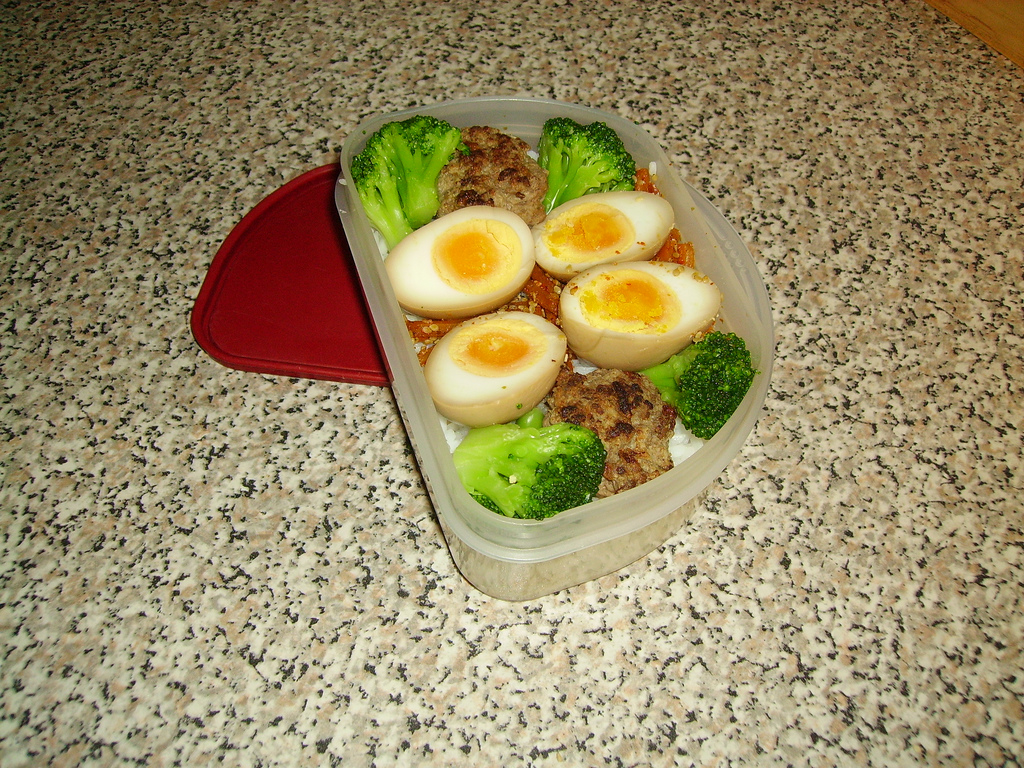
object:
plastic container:
[329, 89, 776, 602]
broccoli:
[336, 113, 453, 250]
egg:
[553, 260, 721, 360]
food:
[347, 102, 761, 523]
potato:
[411, 168, 688, 364]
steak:
[443, 122, 550, 231]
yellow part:
[441, 219, 520, 288]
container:
[189, 95, 777, 604]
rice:
[668, 432, 703, 465]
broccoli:
[542, 119, 629, 217]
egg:
[417, 307, 567, 424]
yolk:
[473, 323, 525, 366]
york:
[580, 269, 663, 325]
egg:
[381, 202, 531, 321]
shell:
[499, 388, 543, 408]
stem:
[449, 428, 504, 478]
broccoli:
[454, 424, 610, 522]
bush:
[518, 427, 609, 522]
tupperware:
[477, 519, 612, 567]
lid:
[191, 160, 378, 401]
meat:
[548, 359, 680, 491]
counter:
[0, 0, 1024, 766]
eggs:
[397, 191, 733, 422]